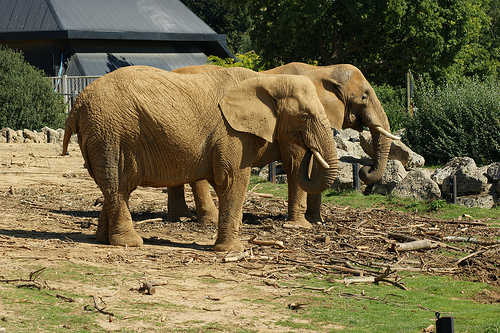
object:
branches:
[324, 217, 500, 276]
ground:
[0, 199, 498, 333]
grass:
[0, 260, 500, 332]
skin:
[130, 83, 203, 139]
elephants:
[58, 64, 339, 252]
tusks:
[378, 126, 402, 145]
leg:
[95, 141, 141, 242]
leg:
[213, 151, 251, 252]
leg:
[87, 136, 143, 246]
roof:
[0, 1, 228, 59]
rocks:
[389, 167, 441, 202]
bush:
[411, 77, 499, 161]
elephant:
[163, 62, 403, 229]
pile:
[332, 125, 500, 209]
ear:
[216, 77, 277, 144]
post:
[348, 162, 362, 191]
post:
[449, 177, 457, 203]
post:
[267, 163, 278, 183]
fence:
[43, 75, 105, 114]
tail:
[58, 109, 77, 157]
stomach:
[134, 129, 210, 189]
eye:
[298, 112, 311, 121]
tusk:
[307, 146, 331, 169]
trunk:
[296, 133, 339, 194]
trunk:
[357, 113, 393, 184]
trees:
[252, 0, 387, 71]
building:
[0, 0, 229, 134]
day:
[0, 0, 500, 333]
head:
[218, 70, 339, 194]